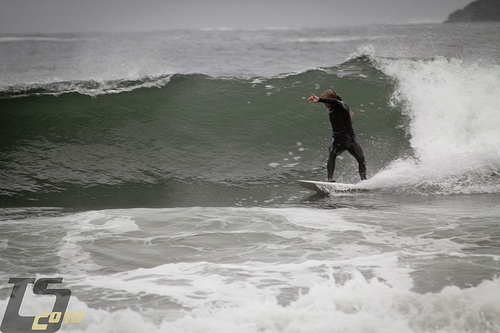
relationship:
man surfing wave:
[306, 88, 370, 182] [369, 51, 498, 192]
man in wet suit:
[306, 88, 370, 182] [327, 103, 368, 184]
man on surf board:
[306, 88, 370, 182] [300, 173, 361, 193]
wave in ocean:
[369, 51, 498, 192] [5, 2, 494, 327]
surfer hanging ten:
[306, 88, 370, 182] [327, 174, 365, 185]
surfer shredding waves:
[306, 88, 370, 182] [369, 51, 498, 192]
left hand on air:
[306, 93, 319, 104] [190, 66, 323, 149]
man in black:
[306, 88, 370, 182] [327, 103, 368, 184]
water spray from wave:
[338, 35, 477, 75] [369, 51, 498, 192]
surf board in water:
[300, 173, 361, 193] [5, 2, 494, 327]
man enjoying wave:
[306, 88, 370, 182] [369, 51, 498, 192]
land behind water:
[443, 0, 499, 25] [5, 2, 494, 327]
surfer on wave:
[306, 88, 370, 182] [369, 51, 498, 192]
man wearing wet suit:
[306, 88, 370, 182] [327, 103, 368, 184]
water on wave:
[5, 2, 494, 327] [369, 51, 498, 192]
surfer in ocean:
[306, 88, 370, 182] [5, 2, 494, 327]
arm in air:
[309, 93, 346, 109] [190, 66, 323, 149]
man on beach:
[306, 89, 367, 183] [5, 2, 494, 327]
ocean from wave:
[5, 2, 494, 327] [369, 51, 498, 192]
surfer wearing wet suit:
[306, 88, 370, 182] [327, 103, 368, 184]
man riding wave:
[306, 88, 370, 182] [369, 51, 498, 192]